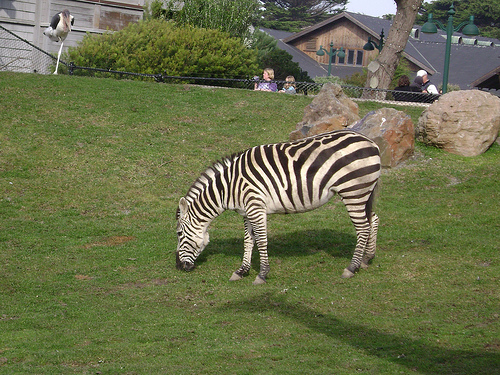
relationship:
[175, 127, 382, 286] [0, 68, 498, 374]
zebra in grass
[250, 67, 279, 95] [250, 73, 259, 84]
woman has camera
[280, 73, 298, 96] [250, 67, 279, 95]
girl with woman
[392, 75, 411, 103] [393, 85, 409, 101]
person wearing black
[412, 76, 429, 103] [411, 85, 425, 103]
person wearing black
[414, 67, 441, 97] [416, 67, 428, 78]
man with cap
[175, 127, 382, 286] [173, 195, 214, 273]
zebra has head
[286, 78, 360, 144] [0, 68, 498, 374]
boulder in grass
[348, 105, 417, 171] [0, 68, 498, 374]
boulder in grass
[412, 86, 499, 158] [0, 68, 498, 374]
boulder in grass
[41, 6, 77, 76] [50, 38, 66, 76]
bird standing on one leg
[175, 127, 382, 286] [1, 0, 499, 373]
zebra in zoo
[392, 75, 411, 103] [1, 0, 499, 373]
person at zoo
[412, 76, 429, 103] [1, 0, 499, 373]
person at zoo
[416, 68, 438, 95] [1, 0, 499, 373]
person at zoo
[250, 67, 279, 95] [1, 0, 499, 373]
person at zoo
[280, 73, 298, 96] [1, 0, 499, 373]
person at zoo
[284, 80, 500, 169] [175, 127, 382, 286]
rocks behind zebra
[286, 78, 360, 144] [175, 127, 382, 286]
rock behind zebra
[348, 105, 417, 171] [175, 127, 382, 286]
rock behind zebra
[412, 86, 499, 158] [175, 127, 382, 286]
rock behind zebra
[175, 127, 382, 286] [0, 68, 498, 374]
zebra eating grass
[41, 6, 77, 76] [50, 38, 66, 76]
stork on one leg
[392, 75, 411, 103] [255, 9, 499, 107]
person in front of building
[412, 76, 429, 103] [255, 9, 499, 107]
person in front of building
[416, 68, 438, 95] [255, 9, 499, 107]
person in front of building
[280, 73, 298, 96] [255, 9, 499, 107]
person in front of building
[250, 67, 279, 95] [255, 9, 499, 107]
person in front of building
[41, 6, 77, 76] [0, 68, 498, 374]
bird walking on grass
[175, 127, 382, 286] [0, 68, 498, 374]
zebra walking on grass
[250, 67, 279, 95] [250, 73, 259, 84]
woman with camera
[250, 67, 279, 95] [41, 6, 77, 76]
woman watching ostrich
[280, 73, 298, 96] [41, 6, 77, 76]
child watching ostrich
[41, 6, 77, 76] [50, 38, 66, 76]
ostrich on one leg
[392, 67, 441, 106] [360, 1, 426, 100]
people near tree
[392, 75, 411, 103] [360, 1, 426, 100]
person near tree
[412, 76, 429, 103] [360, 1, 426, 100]
person near tree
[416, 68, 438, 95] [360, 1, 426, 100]
person near tree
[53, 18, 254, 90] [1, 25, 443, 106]
bush near enclosure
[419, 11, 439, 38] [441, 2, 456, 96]
light on pole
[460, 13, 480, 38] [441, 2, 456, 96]
light on pole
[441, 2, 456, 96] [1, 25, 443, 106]
pole outside fence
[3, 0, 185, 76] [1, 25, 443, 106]
building outside fence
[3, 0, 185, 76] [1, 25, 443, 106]
barn outside fence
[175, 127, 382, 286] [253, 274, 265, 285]
zebra has hoof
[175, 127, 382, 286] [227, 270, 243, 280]
zebra has hoof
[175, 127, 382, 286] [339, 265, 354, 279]
zebra has hoof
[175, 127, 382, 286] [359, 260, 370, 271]
zebra has hoof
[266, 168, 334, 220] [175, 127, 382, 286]
stomach of zebra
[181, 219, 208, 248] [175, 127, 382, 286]
jaw of zebra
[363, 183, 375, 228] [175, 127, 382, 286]
tail of zebra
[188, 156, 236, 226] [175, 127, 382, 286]
neck of zebra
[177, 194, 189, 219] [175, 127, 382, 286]
ear of zebra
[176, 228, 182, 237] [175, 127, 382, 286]
eye of zebra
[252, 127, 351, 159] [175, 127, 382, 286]
back of zebra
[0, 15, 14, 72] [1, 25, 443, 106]
edge of fence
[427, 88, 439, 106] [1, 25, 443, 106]
edge of fence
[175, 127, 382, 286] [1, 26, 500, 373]
zebra in enclosure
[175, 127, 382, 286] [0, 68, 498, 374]
zebra grazing on grass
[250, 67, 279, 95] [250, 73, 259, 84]
tourist with camera